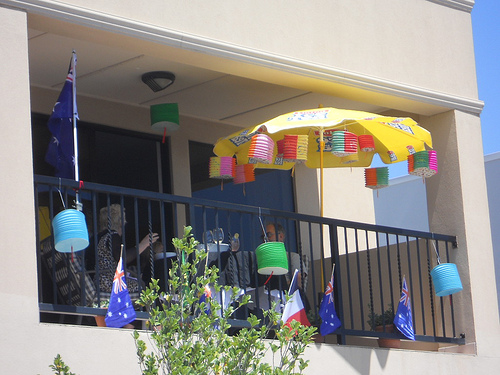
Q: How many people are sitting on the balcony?
A: 2.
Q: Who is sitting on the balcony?
A: A man and woman.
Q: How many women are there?
A: 1.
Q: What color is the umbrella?
A: Yellow.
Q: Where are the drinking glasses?
A: On the table.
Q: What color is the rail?
A: Black.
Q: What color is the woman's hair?
A: Grey.